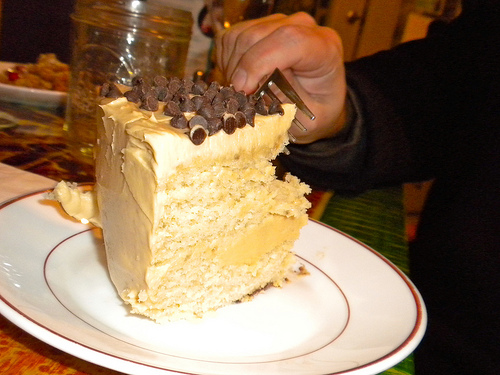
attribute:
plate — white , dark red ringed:
[1, 177, 422, 372]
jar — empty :
[67, 6, 189, 191]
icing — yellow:
[76, 89, 194, 305]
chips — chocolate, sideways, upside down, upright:
[160, 81, 220, 131]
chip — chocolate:
[190, 127, 208, 147]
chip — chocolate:
[170, 114, 215, 137]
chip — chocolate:
[198, 110, 238, 140]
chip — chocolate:
[202, 89, 238, 133]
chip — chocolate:
[216, 113, 237, 130]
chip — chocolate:
[186, 93, 237, 128]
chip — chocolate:
[145, 96, 205, 139]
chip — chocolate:
[158, 87, 217, 122]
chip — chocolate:
[147, 83, 235, 130]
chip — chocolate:
[162, 78, 227, 138]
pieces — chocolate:
[108, 67, 183, 123]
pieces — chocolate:
[94, 60, 230, 137]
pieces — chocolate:
[125, 72, 211, 144]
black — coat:
[347, 55, 439, 257]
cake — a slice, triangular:
[120, 106, 270, 306]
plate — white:
[138, 316, 282, 369]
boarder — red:
[318, 289, 418, 351]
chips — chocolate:
[149, 89, 209, 148]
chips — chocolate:
[162, 103, 228, 143]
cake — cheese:
[104, 89, 290, 336]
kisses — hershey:
[145, 83, 224, 150]